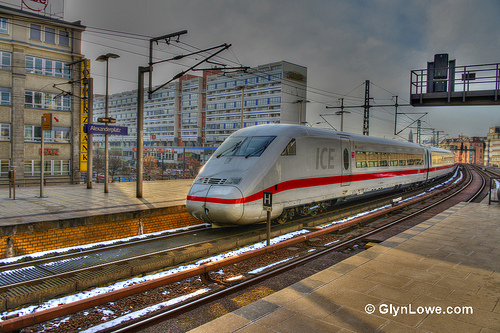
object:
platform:
[0, 174, 188, 228]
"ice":
[313, 144, 338, 169]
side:
[297, 133, 454, 195]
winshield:
[209, 131, 277, 157]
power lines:
[1, 11, 337, 104]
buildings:
[86, 57, 305, 162]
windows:
[348, 144, 427, 174]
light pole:
[104, 48, 111, 197]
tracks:
[0, 165, 485, 332]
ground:
[253, 129, 279, 186]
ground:
[2, 178, 498, 331]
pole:
[38, 115, 44, 196]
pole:
[104, 56, 109, 194]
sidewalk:
[145, 200, 498, 333]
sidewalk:
[1, 177, 195, 228]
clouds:
[214, 6, 445, 108]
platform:
[113, 202, 499, 333]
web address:
[361, 298, 478, 321]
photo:
[1, 1, 498, 330]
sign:
[76, 57, 93, 172]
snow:
[0, 252, 223, 324]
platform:
[407, 52, 498, 108]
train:
[185, 120, 463, 228]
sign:
[257, 189, 278, 244]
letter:
[261, 190, 272, 212]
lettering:
[79, 58, 94, 170]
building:
[0, 2, 93, 188]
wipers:
[244, 140, 271, 159]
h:
[264, 193, 272, 205]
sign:
[80, 115, 123, 193]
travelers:
[39, 146, 97, 273]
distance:
[314, 78, 484, 166]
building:
[437, 135, 484, 164]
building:
[481, 125, 484, 164]